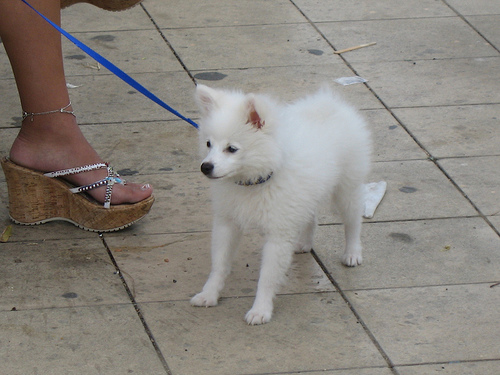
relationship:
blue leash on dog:
[24, 0, 274, 188] [186, 80, 373, 325]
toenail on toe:
[140, 180, 151, 190] [110, 181, 151, 203]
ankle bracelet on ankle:
[17, 97, 75, 126] [31, 111, 66, 140]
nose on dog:
[195, 154, 223, 187] [186, 71, 382, 319]